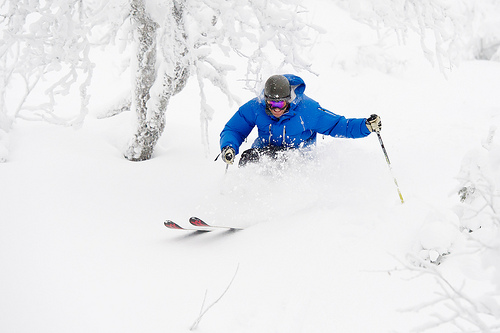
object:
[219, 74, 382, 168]
man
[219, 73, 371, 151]
coat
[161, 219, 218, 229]
skis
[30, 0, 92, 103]
tree branches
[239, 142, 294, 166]
pants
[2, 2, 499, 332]
picture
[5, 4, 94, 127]
tree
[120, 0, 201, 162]
tree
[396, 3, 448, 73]
tree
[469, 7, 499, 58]
tree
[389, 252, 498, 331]
branches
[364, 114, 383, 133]
glove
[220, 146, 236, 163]
glove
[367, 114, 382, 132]
hand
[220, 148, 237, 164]
hand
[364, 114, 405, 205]
pole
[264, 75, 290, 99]
hat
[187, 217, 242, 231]
ski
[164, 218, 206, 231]
ski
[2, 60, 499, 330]
ground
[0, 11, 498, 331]
snow